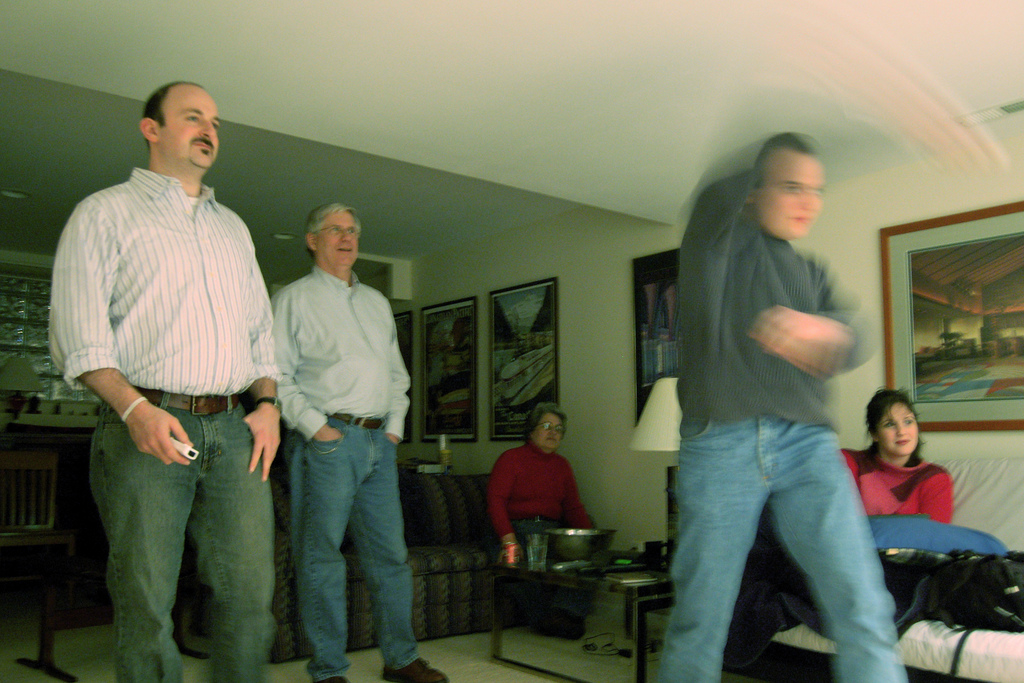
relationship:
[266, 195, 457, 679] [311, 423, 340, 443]
man has hand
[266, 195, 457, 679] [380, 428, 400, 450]
man has hand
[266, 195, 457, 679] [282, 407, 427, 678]
man wearing jeans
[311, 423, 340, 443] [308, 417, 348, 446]
hand in pocket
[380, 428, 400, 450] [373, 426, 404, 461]
hand in pocket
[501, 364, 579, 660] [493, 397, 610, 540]
woman wearing corrective glasses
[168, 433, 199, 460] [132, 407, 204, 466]
remote in hand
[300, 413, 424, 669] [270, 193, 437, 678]
jeans on man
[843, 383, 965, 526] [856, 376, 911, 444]
woman has hair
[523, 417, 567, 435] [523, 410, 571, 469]
glasses on her face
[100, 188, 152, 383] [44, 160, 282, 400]
stripe adorning shirt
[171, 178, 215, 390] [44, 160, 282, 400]
stripe adorning shirt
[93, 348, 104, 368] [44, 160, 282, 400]
stripe adorning shirt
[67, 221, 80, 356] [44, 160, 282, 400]
stripe adorning shirt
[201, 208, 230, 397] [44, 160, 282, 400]
stripe adorning shirt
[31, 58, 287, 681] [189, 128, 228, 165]
man has goatee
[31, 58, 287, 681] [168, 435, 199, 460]
man wears remote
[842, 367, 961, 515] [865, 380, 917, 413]
woman has hair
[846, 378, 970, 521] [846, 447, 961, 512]
woman wears top